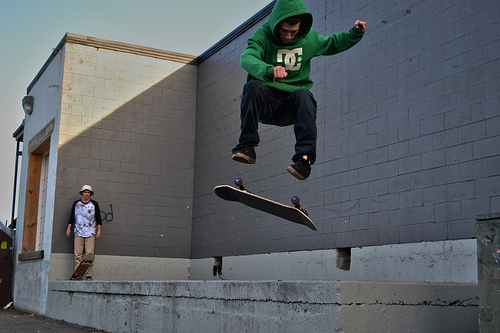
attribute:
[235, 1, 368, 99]
sweatshirt — green, dc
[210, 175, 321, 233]
skateboard — in air, upside down, black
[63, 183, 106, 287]
man — standing, jumping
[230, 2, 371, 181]
man — doing trick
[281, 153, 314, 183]
shoes — black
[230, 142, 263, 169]
shoes — black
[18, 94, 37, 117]
fixture — light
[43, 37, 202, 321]
wall — bricks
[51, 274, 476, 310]
floor — worn, concrete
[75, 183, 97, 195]
hat — white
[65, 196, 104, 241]
shirt — grey, black, white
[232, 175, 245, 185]
wheel — purple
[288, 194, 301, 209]
wheel — rear, purple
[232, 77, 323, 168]
pants — black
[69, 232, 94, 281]
pants — tan